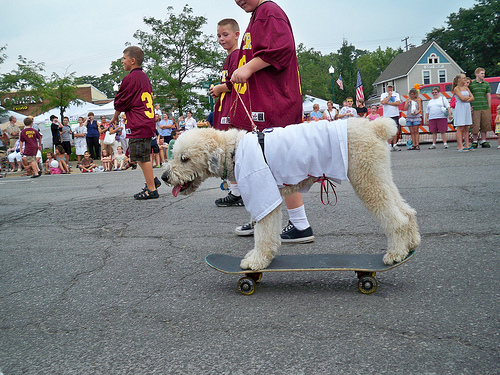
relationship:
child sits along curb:
[26, 146, 130, 176] [392, 134, 484, 158]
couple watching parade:
[453, 62, 494, 156] [15, 1, 449, 311]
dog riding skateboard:
[160, 117, 422, 270] [202, 224, 482, 309]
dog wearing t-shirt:
[160, 117, 422, 270] [233, 118, 346, 222]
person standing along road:
[80, 110, 105, 161] [0, 136, 498, 373]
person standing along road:
[70, 112, 87, 169] [0, 136, 498, 373]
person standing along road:
[44, 112, 67, 152] [0, 136, 498, 373]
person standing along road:
[447, 69, 477, 154] [0, 136, 498, 373]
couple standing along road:
[453, 62, 494, 156] [0, 136, 498, 373]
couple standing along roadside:
[453, 62, 494, 156] [399, 142, 482, 172]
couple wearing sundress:
[453, 62, 494, 156] [454, 90, 474, 128]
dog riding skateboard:
[138, 117, 463, 277] [198, 243, 418, 292]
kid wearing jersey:
[109, 47, 161, 199] [113, 68, 155, 134]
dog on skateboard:
[160, 117, 422, 270] [203, 251, 415, 295]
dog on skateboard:
[160, 117, 422, 270] [203, 246, 415, 293]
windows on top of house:
[421, 51, 449, 87] [365, 40, 477, 99]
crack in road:
[88, 212, 137, 242] [0, 136, 498, 373]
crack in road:
[42, 232, 119, 312] [0, 136, 498, 373]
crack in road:
[130, 185, 199, 223] [0, 136, 498, 373]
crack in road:
[313, 225, 499, 238] [0, 136, 498, 373]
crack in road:
[350, 315, 498, 357] [0, 136, 498, 373]